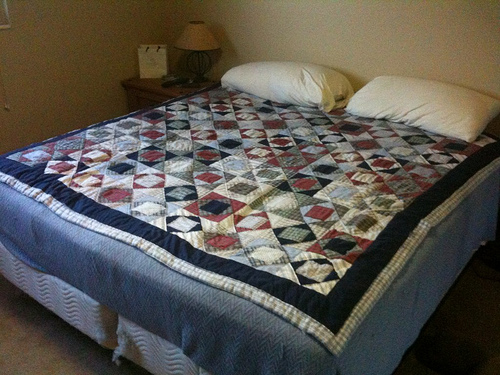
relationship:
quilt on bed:
[4, 45, 498, 339] [1, 52, 499, 373]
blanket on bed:
[1, 85, 497, 370] [1, 52, 499, 373]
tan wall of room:
[169, 0, 497, 150] [3, 6, 484, 359]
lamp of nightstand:
[159, 18, 221, 84] [102, 33, 220, 113]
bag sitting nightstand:
[135, 30, 173, 78] [107, 64, 220, 105]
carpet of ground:
[1, 272, 159, 373] [3, 290, 95, 369]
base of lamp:
[187, 50, 208, 81] [174, 18, 224, 81]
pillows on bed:
[221, 57, 498, 147] [1, 52, 499, 373]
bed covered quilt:
[3, 89, 484, 354] [4, 45, 497, 375]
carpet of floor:
[1, 272, 159, 373] [6, 296, 118, 372]